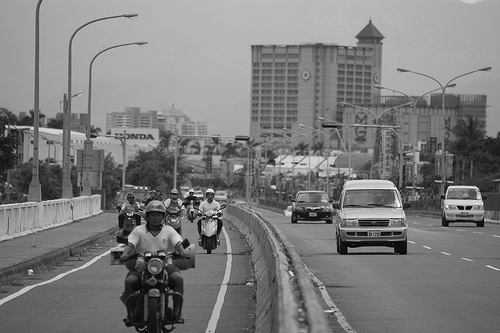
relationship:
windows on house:
[253, 59, 296, 130] [246, 17, 388, 166]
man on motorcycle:
[183, 185, 200, 207] [114, 200, 145, 250]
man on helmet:
[120, 200, 190, 327] [142, 198, 167, 216]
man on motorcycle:
[120, 201, 190, 323] [112, 231, 189, 331]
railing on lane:
[3, 190, 103, 237] [0, 211, 118, 280]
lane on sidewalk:
[13, 213, 108, 271] [12, 205, 112, 275]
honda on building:
[110, 125, 150, 145] [108, 116, 170, 153]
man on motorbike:
[120, 200, 190, 327] [193, 207, 225, 252]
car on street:
[328, 168, 422, 260] [229, 162, 498, 331]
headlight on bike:
[144, 258, 164, 280] [119, 238, 190, 328]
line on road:
[11, 262, 84, 297] [23, 128, 276, 331]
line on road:
[209, 254, 239, 324] [23, 128, 276, 331]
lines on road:
[427, 243, 489, 273] [0, 187, 500, 329]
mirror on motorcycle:
[178, 238, 189, 250] [112, 231, 189, 331]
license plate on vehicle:
[367, 229, 383, 239] [319, 173, 439, 260]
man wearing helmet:
[120, 200, 190, 327] [142, 197, 169, 214]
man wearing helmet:
[193, 190, 222, 223] [201, 182, 220, 197]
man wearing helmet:
[162, 185, 183, 212] [167, 187, 183, 197]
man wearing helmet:
[120, 186, 140, 220] [120, 188, 139, 201]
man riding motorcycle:
[193, 190, 222, 223] [186, 201, 230, 258]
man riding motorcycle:
[120, 200, 190, 327] [117, 232, 194, 331]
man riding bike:
[162, 185, 183, 212] [163, 202, 187, 237]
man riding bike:
[120, 186, 140, 220] [116, 205, 144, 236]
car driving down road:
[332, 180, 411, 255] [333, 256, 490, 306]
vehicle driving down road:
[439, 184, 488, 228] [1, 200, 498, 332]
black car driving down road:
[281, 185, 336, 227] [295, 224, 335, 246]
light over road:
[398, 67, 440, 95] [414, 230, 494, 316]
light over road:
[441, 62, 490, 86] [414, 230, 494, 316]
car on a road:
[332, 180, 411, 255] [65, 183, 498, 331]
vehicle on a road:
[439, 168, 491, 228] [65, 183, 498, 331]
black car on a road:
[290, 190, 334, 224] [65, 183, 498, 331]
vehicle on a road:
[279, 199, 295, 220] [65, 183, 498, 331]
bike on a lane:
[115, 235, 191, 333] [0, 211, 118, 280]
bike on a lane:
[193, 204, 227, 254] [0, 211, 118, 280]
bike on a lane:
[116, 205, 144, 236] [0, 211, 118, 280]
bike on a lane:
[182, 198, 201, 223] [0, 211, 118, 280]